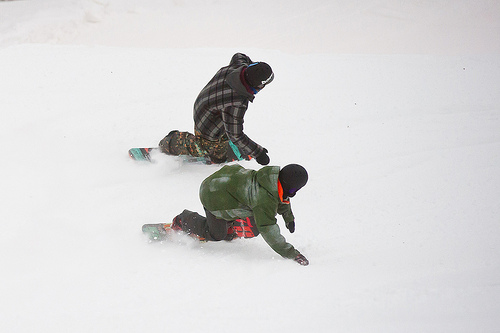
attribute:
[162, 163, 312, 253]
person — playing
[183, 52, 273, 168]
person — playing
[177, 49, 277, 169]
person — standing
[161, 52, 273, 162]
person — playing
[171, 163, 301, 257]
person — playing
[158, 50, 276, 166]
child — looking down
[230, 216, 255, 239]
design — pink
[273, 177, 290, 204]
collar — pink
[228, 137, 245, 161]
design — blue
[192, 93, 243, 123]
stripe — black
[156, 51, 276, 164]
snowboarder — racing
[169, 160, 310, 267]
snowboarder — racing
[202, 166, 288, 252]
jacket — his, green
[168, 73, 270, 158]
jacket — his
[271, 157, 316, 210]
cap — black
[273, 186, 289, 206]
lining — jacket, orange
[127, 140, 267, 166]
snowboard — his, blue, orange, black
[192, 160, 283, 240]
jacket — green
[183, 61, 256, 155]
jacket — black, grey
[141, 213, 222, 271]
snow — kicking up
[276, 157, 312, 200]
hat — black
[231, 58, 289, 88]
helmet — black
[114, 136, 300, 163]
snowboard — multicolored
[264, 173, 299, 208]
neck — snowboarders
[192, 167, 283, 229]
coat — olive green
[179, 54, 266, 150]
coat — gray, plaid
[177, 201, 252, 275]
pants — gray, snow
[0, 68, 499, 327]
ground — snow covered